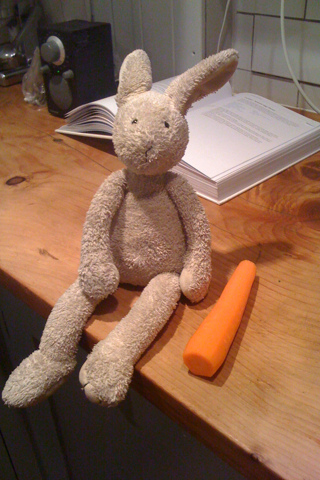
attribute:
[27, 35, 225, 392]
bunny — white, fuzzy, toy, small, stuffed, cute, grey, rabbit, brown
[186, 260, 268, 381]
carrot — orange, fresh, large, big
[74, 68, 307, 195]
book — white, open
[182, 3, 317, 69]
wall — white, ceramic, wood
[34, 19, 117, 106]
speaker — black, big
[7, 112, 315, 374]
table — brown, small